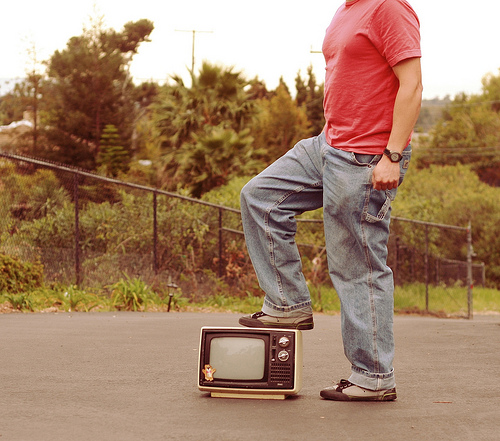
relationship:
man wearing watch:
[241, 0, 426, 402] [380, 140, 412, 170]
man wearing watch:
[241, 0, 426, 402] [379, 144, 407, 165]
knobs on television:
[275, 333, 292, 363] [191, 321, 308, 409]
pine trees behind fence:
[18, 2, 152, 199] [1, 143, 492, 320]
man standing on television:
[241, 0, 426, 402] [195, 325, 303, 399]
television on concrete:
[195, 325, 303, 399] [4, 307, 498, 439]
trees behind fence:
[34, 22, 272, 152] [1, 143, 492, 320]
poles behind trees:
[17, 53, 229, 170] [138, 61, 270, 174]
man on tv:
[241, 0, 426, 402] [189, 292, 304, 416]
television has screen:
[195, 325, 303, 399] [189, 313, 304, 405]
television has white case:
[195, 325, 303, 399] [194, 381, 300, 399]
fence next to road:
[46, 162, 188, 290] [6, 313, 316, 438]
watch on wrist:
[388, 145, 398, 161] [377, 155, 400, 174]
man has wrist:
[319, 9, 428, 139] [377, 155, 400, 174]